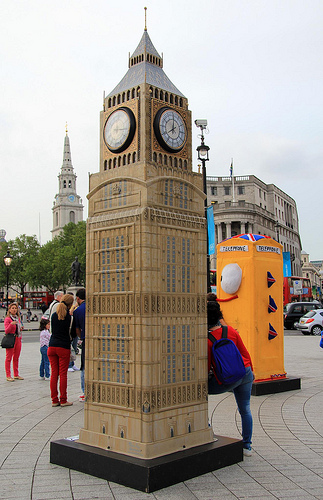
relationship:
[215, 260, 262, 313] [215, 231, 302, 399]
face on booth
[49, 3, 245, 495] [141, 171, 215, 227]
clock tower has arches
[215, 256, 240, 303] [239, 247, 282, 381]
white on booth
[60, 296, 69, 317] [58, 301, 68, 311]
hair in ponytail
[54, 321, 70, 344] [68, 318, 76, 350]
top has sleeves